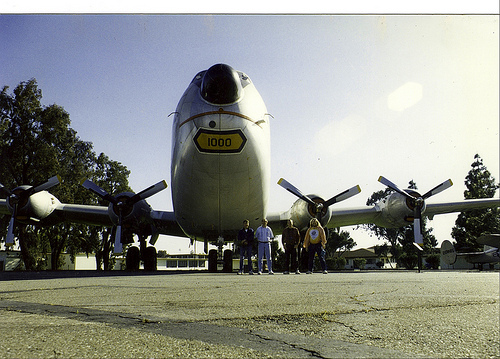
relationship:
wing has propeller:
[268, 178, 498, 246] [377, 176, 451, 250]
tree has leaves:
[5, 78, 99, 277] [0, 79, 76, 201]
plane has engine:
[2, 60, 498, 271] [387, 189, 423, 216]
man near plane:
[253, 217, 276, 275] [2, 60, 498, 271]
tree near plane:
[5, 78, 99, 277] [2, 60, 498, 271]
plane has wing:
[2, 60, 498, 271] [268, 178, 498, 246]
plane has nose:
[2, 60, 498, 271] [199, 64, 244, 102]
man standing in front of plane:
[253, 217, 276, 275] [2, 60, 498, 271]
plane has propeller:
[2, 60, 498, 271] [377, 176, 451, 250]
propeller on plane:
[377, 170, 454, 251] [2, 60, 498, 271]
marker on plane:
[192, 128, 246, 154] [2, 60, 498, 271]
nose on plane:
[199, 64, 244, 102] [2, 60, 498, 271]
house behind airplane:
[330, 244, 396, 271] [4, 63, 496, 274]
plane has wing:
[2, 60, 498, 271] [266, 173, 498, 234]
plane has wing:
[2, 60, 498, 271] [0, 173, 178, 251]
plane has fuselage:
[2, 60, 498, 271] [175, 128, 260, 215]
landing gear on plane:
[124, 232, 160, 275] [2, 60, 498, 271]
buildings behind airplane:
[132, 228, 411, 271] [4, 63, 496, 274]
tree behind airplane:
[365, 183, 436, 266] [4, 63, 496, 274]